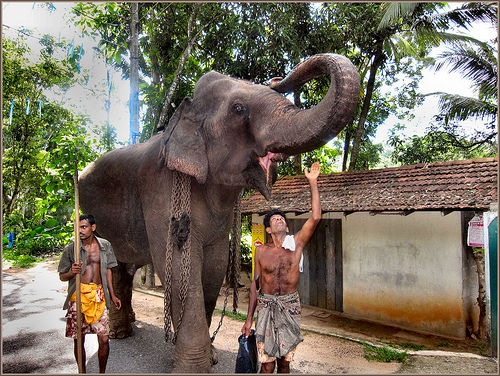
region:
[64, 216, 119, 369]
a man holding a large stick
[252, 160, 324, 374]
a man holding his hand up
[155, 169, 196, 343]
a chain hanging off the elephant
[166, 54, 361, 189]
the face of the elephant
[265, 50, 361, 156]
the trunk of the elephant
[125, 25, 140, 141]
the trunk of the tree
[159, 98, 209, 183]
the ear of the elephant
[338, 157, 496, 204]
the shingles on the building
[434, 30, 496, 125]
the top of a tree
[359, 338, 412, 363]
weeds growing out of the ground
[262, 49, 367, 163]
Elephant's trunk touching his head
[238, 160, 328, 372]
Man with no shirt holding hand up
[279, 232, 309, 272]
White shirt over man's shoulder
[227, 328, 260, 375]
Blue bag in man's hand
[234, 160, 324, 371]
Man underneath elephant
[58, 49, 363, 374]
Elephant walking along with two men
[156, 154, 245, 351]
Chains around elephant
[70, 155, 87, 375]
Long wooden pole in hand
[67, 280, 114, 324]
Yellow clothing around man's waist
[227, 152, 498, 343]
Old building with red shingle rooftop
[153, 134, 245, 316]
Chains are draped around an elelphant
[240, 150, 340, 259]
A man is trying to pet a elephant.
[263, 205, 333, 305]
A man has a white towel on his shoulder.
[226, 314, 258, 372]
a man is carrying a black bag.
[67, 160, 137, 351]
A man is holding a walking stick.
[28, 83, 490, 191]
An elephant is walking pass a building.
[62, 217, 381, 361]
Two men are walking pass a building.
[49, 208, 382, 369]
Two men are walking with an elephant.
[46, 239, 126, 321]
A man is wearing a green shirt.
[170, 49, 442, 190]
An elephant curled its trunk.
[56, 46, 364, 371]
elephant between two men on road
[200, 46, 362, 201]
elephant with pointy mouth and upward curled trunk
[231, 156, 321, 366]
bare chested man raising arm toward elephant overhead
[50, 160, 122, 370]
man with large pole looking to his side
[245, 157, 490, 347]
red tiles over roof of gray and orange buildings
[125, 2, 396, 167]
pole and trees behind elephant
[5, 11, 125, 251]
tall trees behind man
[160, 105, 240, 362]
chains looped around neck and leg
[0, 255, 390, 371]
flat tan path curving behind men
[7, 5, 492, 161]
bright light shining through trees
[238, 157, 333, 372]
skinny man reaching for elephant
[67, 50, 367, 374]
large grey indian elephant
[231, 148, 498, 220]
red tile roofed building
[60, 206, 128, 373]
man wearing an un buttoned shirt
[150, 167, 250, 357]
rusty chains hanging from an elephant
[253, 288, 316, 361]
dirty grey shirt tied around a man's waist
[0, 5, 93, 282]
many bushy green trees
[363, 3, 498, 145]
green palm tree fronds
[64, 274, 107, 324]
yellow material tied around a man's waist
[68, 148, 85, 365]
tall wooden walking stick